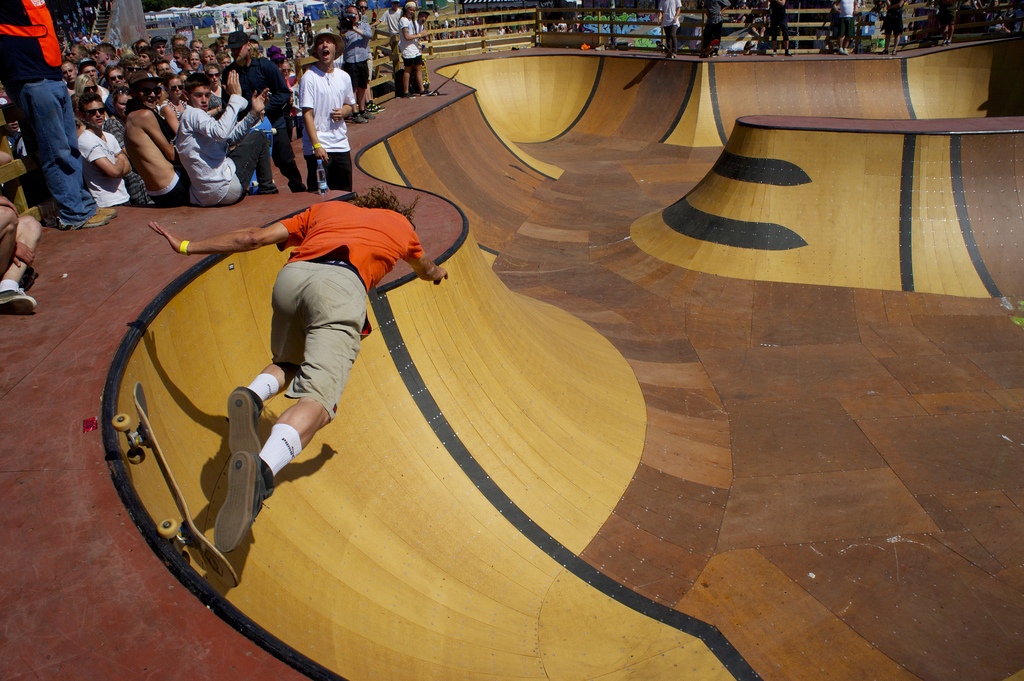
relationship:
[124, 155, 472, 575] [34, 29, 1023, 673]
boy on ramp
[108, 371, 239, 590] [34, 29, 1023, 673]
skateboard on ramp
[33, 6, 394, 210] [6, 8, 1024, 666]
kids are at skatepark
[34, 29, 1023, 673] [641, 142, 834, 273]
ramp has design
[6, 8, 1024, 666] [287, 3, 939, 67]
skatepark has fence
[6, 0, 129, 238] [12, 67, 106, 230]
man has jeans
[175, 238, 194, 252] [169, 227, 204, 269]
bracelet on wrist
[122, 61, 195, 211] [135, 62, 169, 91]
spectator has hat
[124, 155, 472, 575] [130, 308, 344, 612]
boy has shadow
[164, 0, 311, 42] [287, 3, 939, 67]
tent beyond fence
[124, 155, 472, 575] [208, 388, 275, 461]
boy has shoe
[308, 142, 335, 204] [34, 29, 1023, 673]
water bottle on top of ramp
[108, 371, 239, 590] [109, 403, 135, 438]
skateboard has wheel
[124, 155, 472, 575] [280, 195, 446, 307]
boy wearing shirt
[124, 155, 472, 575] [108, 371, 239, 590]
boy falling off skateboard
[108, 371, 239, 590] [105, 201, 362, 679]
skateboard on rail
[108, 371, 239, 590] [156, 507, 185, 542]
skateboard has wheel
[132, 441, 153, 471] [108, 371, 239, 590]
wheel on skateboard